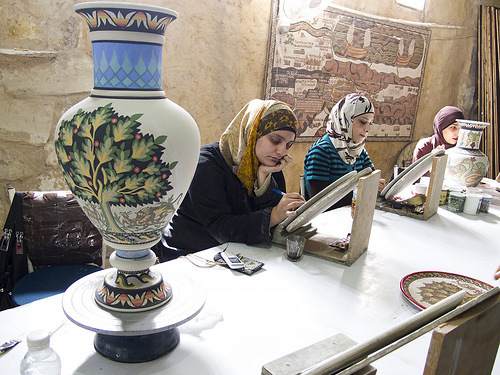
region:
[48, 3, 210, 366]
large vase on display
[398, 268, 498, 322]
decorative plate on the table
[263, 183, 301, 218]
hand holding a writing utensil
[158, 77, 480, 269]
a group of three women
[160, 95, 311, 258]
woman sitting at a table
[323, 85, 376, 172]
hijab around the head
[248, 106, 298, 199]
head resting on the hand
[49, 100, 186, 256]
drawing of a tree on the vase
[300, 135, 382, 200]
black and blue stripes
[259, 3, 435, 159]
decoration on the wall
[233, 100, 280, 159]
Person wearing wrap on head.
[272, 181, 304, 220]
Person using blue marker.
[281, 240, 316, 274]
Dark liquid in glass on table.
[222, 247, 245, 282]
Cellphone sitting on table.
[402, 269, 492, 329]
Decorative plate sitting on table.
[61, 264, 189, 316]
Large decorative pottery on table.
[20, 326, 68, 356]
White cap on bottle.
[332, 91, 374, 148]
Person wearing wrap on head.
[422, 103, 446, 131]
Person wearing wrap on head.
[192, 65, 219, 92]
Brown wall behind woman.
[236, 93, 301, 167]
head of a person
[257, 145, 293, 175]
hand of a person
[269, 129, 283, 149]
eye of a person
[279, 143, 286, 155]
nose of a person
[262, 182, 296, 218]
hand of a person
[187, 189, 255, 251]
arm of a person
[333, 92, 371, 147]
head of a person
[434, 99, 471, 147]
head of a person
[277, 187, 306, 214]
fingers of a person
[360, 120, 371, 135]
nose of a person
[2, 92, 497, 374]
three women sitting on the same side of a long table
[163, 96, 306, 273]
cell phone beside woman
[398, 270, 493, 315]
painted plate with a red rim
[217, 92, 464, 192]
all three women are wearing head coverings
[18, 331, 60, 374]
top of a bottle with a white lid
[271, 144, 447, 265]
two plates on wooden easels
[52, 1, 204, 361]
large painted vase on a wheel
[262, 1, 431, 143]
a hanging woven tapestry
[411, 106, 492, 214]
assorted cups near vase that woman is working on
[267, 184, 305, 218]
woman holding a brush and using her pinkie for stability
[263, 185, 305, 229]
writing utensil in the hand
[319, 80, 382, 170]
hijab on the head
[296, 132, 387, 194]
blue and black stripes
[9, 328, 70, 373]
clear plastic bottle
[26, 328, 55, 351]
white cap on the bottle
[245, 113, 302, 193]
face resting on the hand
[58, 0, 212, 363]
large vase on a pedestal